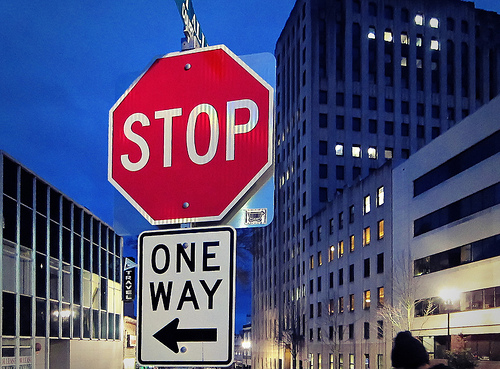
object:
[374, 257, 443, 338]
tree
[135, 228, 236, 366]
sign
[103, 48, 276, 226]
sign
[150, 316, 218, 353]
arrow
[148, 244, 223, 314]
one way